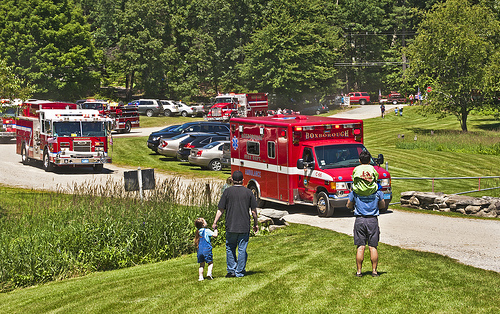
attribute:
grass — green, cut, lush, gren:
[4, 105, 499, 312]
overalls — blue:
[195, 226, 214, 264]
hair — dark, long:
[359, 147, 371, 164]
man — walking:
[212, 166, 260, 276]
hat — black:
[229, 166, 245, 179]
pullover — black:
[217, 182, 261, 235]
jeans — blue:
[221, 232, 253, 278]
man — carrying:
[350, 184, 389, 275]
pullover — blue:
[348, 187, 383, 215]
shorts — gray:
[350, 215, 382, 247]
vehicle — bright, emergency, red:
[226, 107, 382, 218]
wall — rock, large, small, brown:
[400, 185, 500, 220]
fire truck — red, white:
[11, 96, 117, 173]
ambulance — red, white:
[224, 116, 377, 219]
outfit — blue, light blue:
[194, 226, 211, 267]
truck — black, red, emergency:
[384, 91, 407, 105]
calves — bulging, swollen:
[356, 247, 378, 266]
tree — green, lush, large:
[385, 3, 499, 140]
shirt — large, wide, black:
[215, 184, 255, 238]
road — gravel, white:
[0, 106, 499, 269]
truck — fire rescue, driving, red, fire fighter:
[10, 98, 112, 172]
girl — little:
[351, 144, 382, 196]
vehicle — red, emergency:
[10, 92, 116, 172]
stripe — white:
[10, 126, 30, 136]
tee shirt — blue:
[347, 188, 382, 214]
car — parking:
[188, 141, 235, 167]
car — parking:
[177, 131, 234, 160]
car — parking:
[158, 129, 218, 158]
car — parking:
[148, 117, 230, 151]